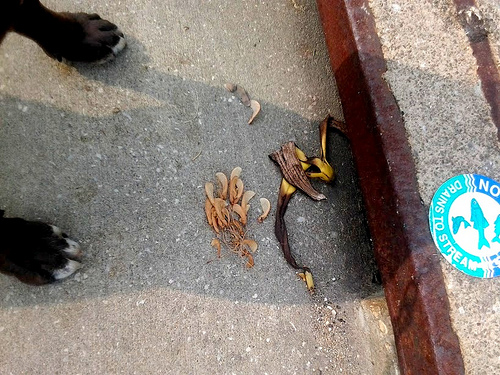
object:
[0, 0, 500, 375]
scene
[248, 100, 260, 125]
seed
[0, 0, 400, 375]
ground